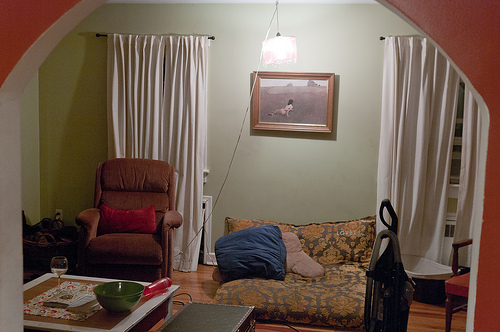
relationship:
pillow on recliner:
[98, 203, 158, 237] [69, 148, 180, 270]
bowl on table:
[93, 281, 144, 314] [31, 264, 167, 329]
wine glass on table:
[45, 252, 69, 291] [31, 264, 167, 329]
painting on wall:
[246, 69, 336, 144] [250, 141, 341, 197]